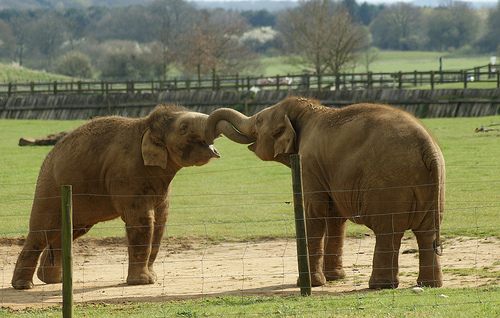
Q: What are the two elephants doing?
A: Greeting each other.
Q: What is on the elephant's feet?
A: Toe nails.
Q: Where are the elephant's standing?
A: On the brown pen's patch.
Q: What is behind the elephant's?
A: Sturdy fencing.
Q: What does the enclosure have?
A: Wooden fencing and logs.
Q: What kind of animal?
A: Elephant.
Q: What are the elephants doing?
A: Playing.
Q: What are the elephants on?
A: Dirt.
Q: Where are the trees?
A: Behind the elephants.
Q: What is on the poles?
A: Wire.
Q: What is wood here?
A: The fence.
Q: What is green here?
A: Grass.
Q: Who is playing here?
A: The elephants.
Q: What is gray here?
A: Elephants.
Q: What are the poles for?
A: The fence.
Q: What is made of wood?
A: The fence of the pen.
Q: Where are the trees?
A: The trees are in the background of the pen.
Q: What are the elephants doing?
A: They are playing with each other.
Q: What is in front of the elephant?
A: Grass.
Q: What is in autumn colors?
A: Several trees in the middle distance.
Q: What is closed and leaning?
A: The long grey fence.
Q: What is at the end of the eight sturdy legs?
A: Eight sturdy feet.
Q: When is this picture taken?
A: During the day.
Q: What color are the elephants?
A: Gray.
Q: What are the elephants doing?
A: Kissing.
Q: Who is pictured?
A: No one.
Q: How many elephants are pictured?
A: Two.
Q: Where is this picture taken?
A: Zoo.